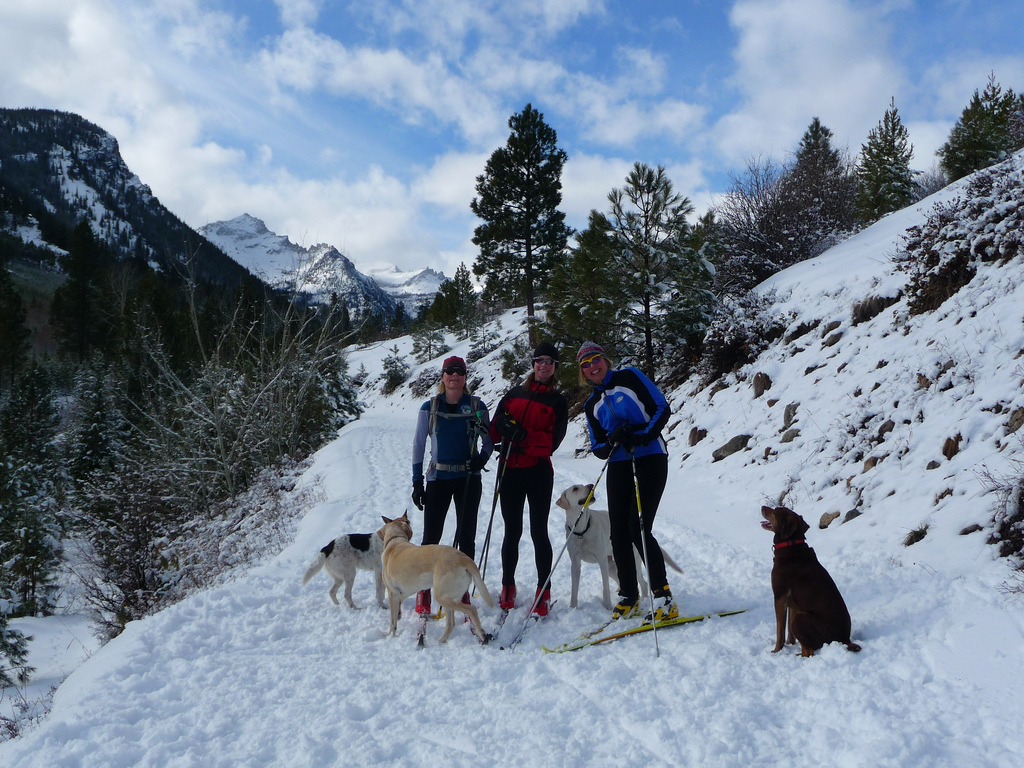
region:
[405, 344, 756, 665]
three women on skiis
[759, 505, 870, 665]
the dog is brown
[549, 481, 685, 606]
white dog behind woman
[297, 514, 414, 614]
dog is white and black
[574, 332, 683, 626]
woman wearing blue, black and white jacket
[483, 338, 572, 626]
woman wearing red and black jacket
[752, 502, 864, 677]
dog has red collar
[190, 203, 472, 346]
mountain covered in snow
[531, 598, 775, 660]
the skiis are yellow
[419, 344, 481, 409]
the head of a woman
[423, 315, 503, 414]
the face of a woman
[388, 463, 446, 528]
the hand of a woman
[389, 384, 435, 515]
the arm of a woman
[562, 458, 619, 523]
the head of a dog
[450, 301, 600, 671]
a woman on skies in the snow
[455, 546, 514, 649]
the tail of a dog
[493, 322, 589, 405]
a woman wearing a hat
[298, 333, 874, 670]
Three women and four dogs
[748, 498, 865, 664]
Brown dog is siting in the snow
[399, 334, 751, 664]
Three women wearing snowsuits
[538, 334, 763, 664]
Woman in blue, black and white coat wearing skis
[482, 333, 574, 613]
Woman in red and black coat wearing black pants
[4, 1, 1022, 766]
Women in the outdoor with their dogs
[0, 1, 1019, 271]
Blue sky with white clouds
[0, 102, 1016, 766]
Mountains and trail covered with snow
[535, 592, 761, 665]
Long yellow skis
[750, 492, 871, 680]
a black dog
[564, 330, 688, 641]
a woman wearing a blue and black jacket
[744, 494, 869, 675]
a black dog wearing a red collar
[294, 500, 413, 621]
a black and white dog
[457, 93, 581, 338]
a tree on the mountain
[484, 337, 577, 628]
a person wearing red shoes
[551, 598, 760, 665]
a set of skis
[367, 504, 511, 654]
a tan colored dog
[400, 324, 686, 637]
a group of people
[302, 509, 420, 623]
a black and white dog with upright ears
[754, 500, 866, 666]
a mostly black dog sitting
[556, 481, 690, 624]
a white Labrador retriever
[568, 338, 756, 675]
woman with yellow skis and blue ski jacket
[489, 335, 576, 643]
man wearing black and red outfit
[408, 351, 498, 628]
woman wearing black pants and blue and white jacket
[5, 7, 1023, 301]
a blue sky with white clouds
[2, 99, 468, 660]
some mountains with snow on them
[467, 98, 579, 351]
a tall evergreen tree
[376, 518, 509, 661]
a yellow labrador retriever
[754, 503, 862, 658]
Black dog sitting on the snow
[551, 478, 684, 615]
White dog sitting on the snow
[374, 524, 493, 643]
Beige dog sitting on the snow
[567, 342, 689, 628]
Woman wearing blue, white and black jacket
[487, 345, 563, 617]
Woman wearing red and black jacket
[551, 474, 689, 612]
White dog staring at a woman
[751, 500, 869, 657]
Black dog staring at a woman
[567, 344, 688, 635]
Woman is standing on two skiis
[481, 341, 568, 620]
Woman is holding a ski pole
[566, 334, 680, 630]
Woman is holding a ski pole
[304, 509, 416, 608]
the black and white dog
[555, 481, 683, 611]
the light tan dog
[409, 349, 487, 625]
the person in the ski outfit standing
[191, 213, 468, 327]
snow covered rocky mountains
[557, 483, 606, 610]
white dog looking up